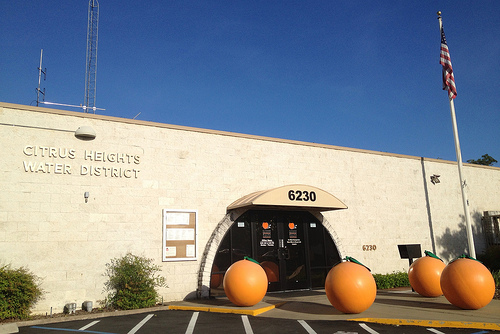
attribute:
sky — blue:
[176, 29, 296, 103]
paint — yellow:
[364, 314, 406, 327]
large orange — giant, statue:
[321, 257, 383, 314]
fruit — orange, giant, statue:
[329, 256, 379, 317]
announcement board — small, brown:
[160, 208, 198, 261]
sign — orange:
[257, 216, 283, 240]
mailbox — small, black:
[396, 241, 423, 258]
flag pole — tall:
[430, 10, 477, 263]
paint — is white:
[23, 200, 69, 228]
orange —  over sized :
[447, 257, 488, 312]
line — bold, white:
[186, 309, 198, 332]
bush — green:
[100, 250, 165, 310]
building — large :
[0, 101, 497, 320]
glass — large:
[210, 210, 347, 297]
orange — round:
[298, 244, 393, 327]